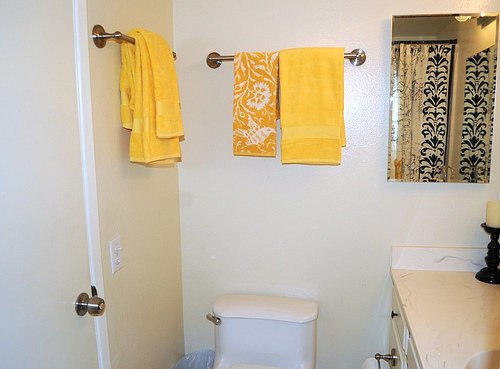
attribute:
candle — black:
[483, 201, 498, 228]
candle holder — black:
[475, 220, 497, 285]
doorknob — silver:
[72, 287, 108, 322]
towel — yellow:
[226, 50, 277, 163]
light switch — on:
[101, 222, 135, 273]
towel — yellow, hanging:
[116, 25, 187, 173]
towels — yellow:
[200, 24, 378, 185]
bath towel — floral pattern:
[222, 50, 282, 166]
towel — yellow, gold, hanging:
[278, 46, 345, 164]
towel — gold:
[232, 50, 276, 159]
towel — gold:
[121, 29, 185, 170]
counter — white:
[384, 238, 496, 360]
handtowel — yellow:
[119, 30, 183, 139]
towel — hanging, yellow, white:
[224, 47, 280, 161]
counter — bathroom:
[388, 266, 485, 366]